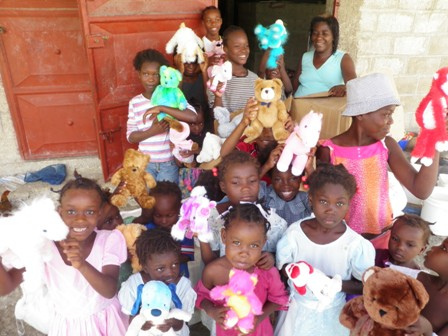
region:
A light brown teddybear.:
[242, 75, 291, 142]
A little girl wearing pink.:
[0, 162, 127, 334]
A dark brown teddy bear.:
[338, 264, 430, 334]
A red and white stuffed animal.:
[283, 258, 342, 306]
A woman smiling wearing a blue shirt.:
[290, 9, 359, 99]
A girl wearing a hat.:
[314, 70, 447, 236]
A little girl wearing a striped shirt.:
[123, 48, 203, 170]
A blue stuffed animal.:
[253, 17, 291, 76]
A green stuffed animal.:
[146, 64, 192, 120]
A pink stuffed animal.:
[211, 267, 266, 334]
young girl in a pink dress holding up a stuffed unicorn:
[0, 165, 133, 334]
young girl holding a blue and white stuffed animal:
[117, 224, 198, 335]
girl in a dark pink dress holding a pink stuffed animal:
[195, 198, 291, 335]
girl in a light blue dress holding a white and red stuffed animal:
[277, 160, 378, 335]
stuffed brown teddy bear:
[339, 265, 435, 335]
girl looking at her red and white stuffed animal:
[319, 67, 447, 249]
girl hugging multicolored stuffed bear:
[126, 49, 203, 182]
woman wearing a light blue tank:
[294, 11, 358, 96]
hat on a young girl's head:
[339, 69, 401, 118]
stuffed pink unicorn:
[275, 108, 324, 176]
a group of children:
[17, 11, 447, 333]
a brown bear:
[344, 267, 431, 334]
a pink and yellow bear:
[210, 271, 263, 330]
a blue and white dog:
[128, 283, 187, 329]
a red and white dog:
[283, 263, 350, 316]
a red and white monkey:
[409, 71, 446, 172]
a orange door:
[6, 0, 96, 162]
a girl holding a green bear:
[133, 55, 198, 151]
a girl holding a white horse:
[8, 183, 121, 333]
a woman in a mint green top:
[296, 11, 358, 98]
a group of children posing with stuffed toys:
[1, 6, 447, 334]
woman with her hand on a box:
[289, 12, 356, 140]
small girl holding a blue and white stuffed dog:
[118, 228, 196, 334]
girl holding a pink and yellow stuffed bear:
[198, 196, 288, 335]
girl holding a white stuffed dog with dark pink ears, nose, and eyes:
[275, 162, 374, 334]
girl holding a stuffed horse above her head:
[259, 110, 323, 222]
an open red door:
[82, 0, 337, 181]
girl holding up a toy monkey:
[314, 68, 447, 233]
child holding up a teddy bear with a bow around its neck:
[222, 78, 294, 152]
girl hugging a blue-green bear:
[127, 49, 199, 153]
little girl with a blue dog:
[123, 230, 186, 334]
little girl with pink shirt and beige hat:
[343, 71, 398, 198]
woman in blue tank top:
[293, 11, 345, 90]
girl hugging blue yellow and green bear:
[130, 44, 188, 134]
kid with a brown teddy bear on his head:
[247, 76, 288, 147]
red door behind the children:
[74, 5, 145, 181]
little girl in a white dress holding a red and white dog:
[282, 171, 365, 332]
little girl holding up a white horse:
[260, 103, 325, 218]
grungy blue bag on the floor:
[23, 161, 69, 184]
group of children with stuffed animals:
[63, 145, 439, 331]